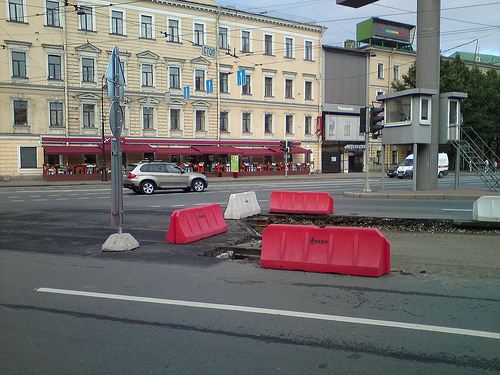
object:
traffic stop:
[368, 105, 386, 133]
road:
[1, 205, 221, 264]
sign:
[110, 139, 124, 228]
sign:
[104, 45, 126, 102]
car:
[121, 158, 209, 194]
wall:
[201, 31, 310, 137]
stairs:
[447, 123, 499, 195]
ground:
[0, 248, 499, 374]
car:
[385, 163, 400, 178]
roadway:
[333, 190, 498, 221]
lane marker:
[34, 286, 499, 340]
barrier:
[259, 223, 391, 278]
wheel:
[191, 178, 208, 193]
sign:
[205, 77, 214, 94]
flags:
[176, 70, 253, 101]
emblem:
[236, 69, 247, 87]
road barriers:
[166, 201, 228, 245]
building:
[0, 0, 329, 181]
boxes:
[375, 87, 437, 145]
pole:
[415, 0, 440, 191]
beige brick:
[0, 138, 17, 173]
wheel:
[139, 180, 157, 195]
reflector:
[257, 221, 387, 277]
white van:
[393, 151, 448, 179]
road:
[0, 177, 333, 245]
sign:
[107, 102, 126, 139]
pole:
[115, 60, 122, 230]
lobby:
[42, 144, 314, 182]